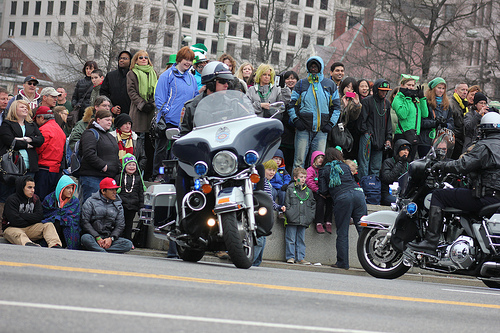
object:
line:
[0, 297, 399, 333]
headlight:
[206, 147, 243, 179]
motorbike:
[354, 144, 497, 291]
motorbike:
[158, 87, 287, 270]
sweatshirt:
[3, 173, 45, 227]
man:
[286, 55, 347, 169]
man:
[357, 79, 394, 191]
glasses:
[308, 63, 324, 68]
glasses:
[137, 56, 149, 60]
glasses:
[27, 81, 39, 86]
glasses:
[216, 79, 228, 85]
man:
[81, 175, 136, 253]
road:
[0, 234, 499, 333]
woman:
[126, 49, 158, 181]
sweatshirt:
[53, 175, 76, 207]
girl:
[388, 73, 428, 147]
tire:
[220, 211, 253, 269]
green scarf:
[132, 63, 158, 102]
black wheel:
[355, 222, 412, 281]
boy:
[152, 46, 198, 182]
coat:
[154, 64, 200, 130]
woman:
[418, 77, 455, 159]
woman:
[0, 100, 45, 206]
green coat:
[387, 88, 431, 136]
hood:
[304, 53, 323, 79]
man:
[1, 176, 66, 250]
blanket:
[40, 190, 84, 248]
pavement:
[0, 242, 499, 332]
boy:
[278, 168, 318, 265]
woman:
[150, 45, 198, 183]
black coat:
[99, 48, 130, 114]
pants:
[327, 189, 371, 270]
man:
[172, 60, 281, 243]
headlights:
[243, 150, 257, 172]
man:
[77, 175, 136, 253]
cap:
[98, 177, 122, 191]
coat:
[391, 89, 429, 137]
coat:
[286, 55, 342, 136]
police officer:
[406, 111, 500, 254]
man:
[98, 51, 132, 114]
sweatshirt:
[362, 95, 391, 147]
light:
[190, 159, 209, 177]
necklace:
[123, 173, 136, 193]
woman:
[317, 145, 373, 271]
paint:
[294, 176, 301, 186]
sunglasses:
[214, 76, 232, 85]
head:
[175, 45, 196, 71]